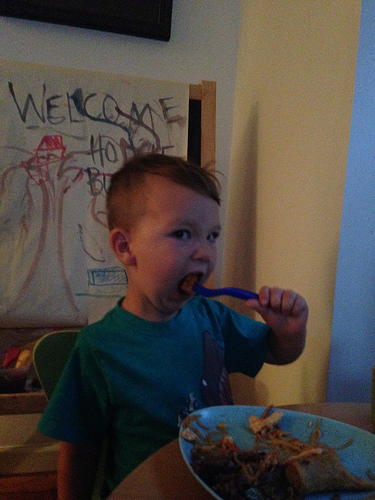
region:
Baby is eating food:
[100, 161, 310, 376]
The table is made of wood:
[133, 456, 172, 495]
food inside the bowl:
[219, 415, 341, 496]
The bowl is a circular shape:
[177, 405, 317, 486]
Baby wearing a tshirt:
[47, 295, 295, 423]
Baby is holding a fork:
[189, 270, 294, 331]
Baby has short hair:
[111, 142, 217, 223]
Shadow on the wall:
[209, 102, 273, 219]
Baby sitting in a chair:
[11, 324, 155, 440]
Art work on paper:
[2, 82, 131, 278]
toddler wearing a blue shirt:
[88, 142, 324, 399]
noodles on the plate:
[237, 408, 297, 448]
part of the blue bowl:
[331, 425, 351, 438]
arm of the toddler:
[53, 436, 98, 499]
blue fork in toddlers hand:
[191, 282, 259, 305]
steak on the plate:
[287, 448, 366, 499]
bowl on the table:
[171, 404, 372, 496]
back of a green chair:
[36, 338, 67, 374]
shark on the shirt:
[189, 321, 234, 408]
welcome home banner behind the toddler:
[24, 82, 192, 154]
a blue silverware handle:
[191, 283, 256, 304]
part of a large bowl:
[175, 402, 371, 498]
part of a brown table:
[103, 400, 374, 498]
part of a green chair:
[26, 327, 81, 389]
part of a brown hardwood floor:
[0, 472, 54, 499]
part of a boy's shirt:
[37, 302, 279, 496]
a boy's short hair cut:
[102, 150, 225, 237]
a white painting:
[1, 60, 198, 329]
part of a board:
[183, 81, 221, 169]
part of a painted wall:
[232, 0, 357, 210]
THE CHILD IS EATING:
[110, 157, 345, 490]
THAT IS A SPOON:
[192, 277, 259, 303]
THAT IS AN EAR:
[110, 231, 145, 262]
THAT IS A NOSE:
[181, 240, 219, 264]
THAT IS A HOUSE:
[157, 214, 185, 256]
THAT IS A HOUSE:
[199, 224, 227, 256]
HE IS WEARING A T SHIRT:
[97, 358, 132, 404]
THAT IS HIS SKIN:
[127, 213, 154, 266]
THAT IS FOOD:
[200, 427, 267, 463]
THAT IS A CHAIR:
[36, 344, 64, 369]